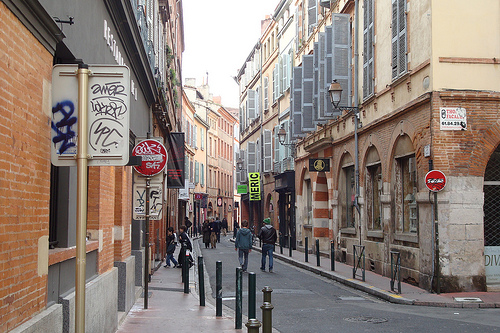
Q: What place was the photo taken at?
A: It was taken at the sidewalk.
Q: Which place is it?
A: It is a sidewalk.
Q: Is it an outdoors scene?
A: Yes, it is outdoors.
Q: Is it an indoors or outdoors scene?
A: It is outdoors.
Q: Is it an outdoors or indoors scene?
A: It is outdoors.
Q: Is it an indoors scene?
A: No, it is outdoors.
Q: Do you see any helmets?
A: No, there are no helmets.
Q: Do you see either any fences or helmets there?
A: No, there are no helmets or fences.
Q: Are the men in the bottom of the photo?
A: Yes, the men are in the bottom of the image.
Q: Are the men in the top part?
A: No, the men are in the bottom of the image.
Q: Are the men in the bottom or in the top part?
A: The men are in the bottom of the image.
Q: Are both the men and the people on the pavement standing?
A: Yes, both the men and the people are standing.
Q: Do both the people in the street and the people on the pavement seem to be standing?
A: Yes, both the men and the people are standing.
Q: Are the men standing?
A: Yes, the men are standing.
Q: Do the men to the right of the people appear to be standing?
A: Yes, the men are standing.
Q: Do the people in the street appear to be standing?
A: Yes, the men are standing.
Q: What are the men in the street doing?
A: The men are standing.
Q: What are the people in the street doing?
A: The men are standing.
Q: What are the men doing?
A: The men are standing.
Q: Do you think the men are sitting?
A: No, the men are standing.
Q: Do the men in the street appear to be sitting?
A: No, the men are standing.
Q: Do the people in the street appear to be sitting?
A: No, the men are standing.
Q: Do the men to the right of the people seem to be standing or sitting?
A: The men are standing.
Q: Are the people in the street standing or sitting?
A: The men are standing.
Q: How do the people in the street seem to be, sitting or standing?
A: The men are standing.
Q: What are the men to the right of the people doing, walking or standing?
A: The men are standing.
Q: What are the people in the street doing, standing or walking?
A: The men are standing.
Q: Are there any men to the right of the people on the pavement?
A: Yes, there are men to the right of the people.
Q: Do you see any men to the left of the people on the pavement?
A: No, the men are to the right of the people.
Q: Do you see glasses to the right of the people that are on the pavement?
A: No, there are men to the right of the people.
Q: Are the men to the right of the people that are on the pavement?
A: Yes, the men are to the right of the people.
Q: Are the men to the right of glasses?
A: No, the men are to the right of the people.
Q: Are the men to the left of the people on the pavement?
A: No, the men are to the right of the people.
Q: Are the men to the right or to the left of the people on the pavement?
A: The men are to the right of the people.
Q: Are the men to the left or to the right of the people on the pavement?
A: The men are to the right of the people.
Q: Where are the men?
A: The men are in the street.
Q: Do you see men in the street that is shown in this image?
A: Yes, there are men in the street.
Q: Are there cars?
A: No, there are no cars.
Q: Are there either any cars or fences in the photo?
A: No, there are no cars or fences.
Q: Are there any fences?
A: No, there are no fences.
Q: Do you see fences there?
A: No, there are no fences.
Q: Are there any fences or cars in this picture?
A: No, there are no fences or cars.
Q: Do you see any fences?
A: No, there are no fences.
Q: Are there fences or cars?
A: No, there are no fences or cars.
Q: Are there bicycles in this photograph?
A: No, there are no bicycles.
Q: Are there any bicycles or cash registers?
A: No, there are no bicycles or cash registers.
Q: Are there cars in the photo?
A: No, there are no cars.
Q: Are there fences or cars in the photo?
A: No, there are no cars or fences.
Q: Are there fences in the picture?
A: No, there are no fences.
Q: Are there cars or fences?
A: No, there are no fences or cars.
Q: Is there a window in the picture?
A: Yes, there are windows.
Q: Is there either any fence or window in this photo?
A: Yes, there are windows.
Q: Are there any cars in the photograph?
A: No, there are no cars.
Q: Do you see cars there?
A: No, there are no cars.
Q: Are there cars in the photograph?
A: No, there are no cars.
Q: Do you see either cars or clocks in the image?
A: No, there are no cars or clocks.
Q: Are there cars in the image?
A: No, there are no cars.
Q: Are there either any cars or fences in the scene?
A: No, there are no cars or fences.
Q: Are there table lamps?
A: No, there are no table lamps.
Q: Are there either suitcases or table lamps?
A: No, there are no table lamps or suitcases.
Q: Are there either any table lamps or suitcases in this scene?
A: No, there are no table lamps or suitcases.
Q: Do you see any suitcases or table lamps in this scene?
A: No, there are no table lamps or suitcases.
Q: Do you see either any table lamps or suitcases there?
A: No, there are no table lamps or suitcases.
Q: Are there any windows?
A: Yes, there are windows.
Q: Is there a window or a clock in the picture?
A: Yes, there are windows.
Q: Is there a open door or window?
A: Yes, there are open windows.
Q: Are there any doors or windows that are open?
A: Yes, the windows are open.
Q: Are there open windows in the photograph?
A: Yes, there are open windows.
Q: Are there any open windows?
A: Yes, there are open windows.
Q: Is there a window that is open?
A: Yes, there are windows that are open.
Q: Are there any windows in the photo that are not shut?
A: Yes, there are open windows.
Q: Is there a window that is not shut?
A: Yes, there are open windows.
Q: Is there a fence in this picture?
A: No, there are no fences.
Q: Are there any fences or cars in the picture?
A: No, there are no fences or cars.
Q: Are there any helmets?
A: No, there are no helmets.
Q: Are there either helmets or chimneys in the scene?
A: No, there are no helmets or chimneys.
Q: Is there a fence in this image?
A: No, there are no fences.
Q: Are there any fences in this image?
A: No, there are no fences.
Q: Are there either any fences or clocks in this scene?
A: No, there are no fences or clocks.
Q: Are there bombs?
A: No, there are no bombs.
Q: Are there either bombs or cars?
A: No, there are no bombs or cars.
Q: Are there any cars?
A: No, there are no cars.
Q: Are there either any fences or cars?
A: No, there are no cars or fences.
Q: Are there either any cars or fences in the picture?
A: No, there are no cars or fences.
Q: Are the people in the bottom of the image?
A: Yes, the people are in the bottom of the image.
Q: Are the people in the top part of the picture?
A: No, the people are in the bottom of the image.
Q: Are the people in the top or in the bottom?
A: The people are in the bottom of the image.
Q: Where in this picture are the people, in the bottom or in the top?
A: The people are in the bottom of the image.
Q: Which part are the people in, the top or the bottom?
A: The people are in the bottom of the image.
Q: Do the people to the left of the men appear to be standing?
A: Yes, the people are standing.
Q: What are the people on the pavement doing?
A: The people are standing.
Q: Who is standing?
A: The people are standing.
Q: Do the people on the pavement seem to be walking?
A: No, the people are standing.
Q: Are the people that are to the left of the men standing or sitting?
A: The people are standing.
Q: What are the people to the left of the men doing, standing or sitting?
A: The people are standing.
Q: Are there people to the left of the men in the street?
A: Yes, there are people to the left of the men.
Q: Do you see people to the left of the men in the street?
A: Yes, there are people to the left of the men.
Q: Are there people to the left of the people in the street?
A: Yes, there are people to the left of the men.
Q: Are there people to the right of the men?
A: No, the people are to the left of the men.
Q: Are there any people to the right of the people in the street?
A: No, the people are to the left of the men.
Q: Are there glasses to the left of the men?
A: No, there are people to the left of the men.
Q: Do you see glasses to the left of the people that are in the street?
A: No, there are people to the left of the men.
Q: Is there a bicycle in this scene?
A: No, there are no bicycles.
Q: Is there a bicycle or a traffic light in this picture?
A: No, there are no bicycles or traffic lights.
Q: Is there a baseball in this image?
A: No, there are no baseballs.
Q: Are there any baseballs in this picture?
A: No, there are no baseballs.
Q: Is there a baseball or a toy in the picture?
A: No, there are no baseballs or toys.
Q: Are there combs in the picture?
A: No, there are no combs.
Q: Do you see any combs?
A: No, there are no combs.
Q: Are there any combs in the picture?
A: No, there are no combs.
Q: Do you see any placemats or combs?
A: No, there are no combs or placemats.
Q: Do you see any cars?
A: No, there are no cars.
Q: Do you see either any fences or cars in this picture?
A: No, there are no cars or fences.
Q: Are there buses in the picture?
A: No, there are no buses.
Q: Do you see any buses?
A: No, there are no buses.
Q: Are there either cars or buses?
A: No, there are no buses or cars.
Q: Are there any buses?
A: No, there are no buses.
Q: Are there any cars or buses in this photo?
A: No, there are no buses or cars.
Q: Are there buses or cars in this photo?
A: No, there are no buses or cars.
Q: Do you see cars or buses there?
A: No, there are no buses or cars.